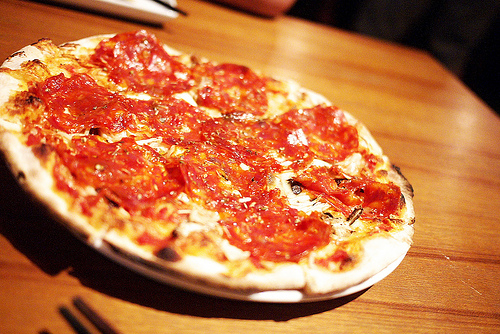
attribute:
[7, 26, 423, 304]
pizza — wooden, dining, freshly cooked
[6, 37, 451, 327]
table — brown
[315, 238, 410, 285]
part — burned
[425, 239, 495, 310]
lines — dark, brown